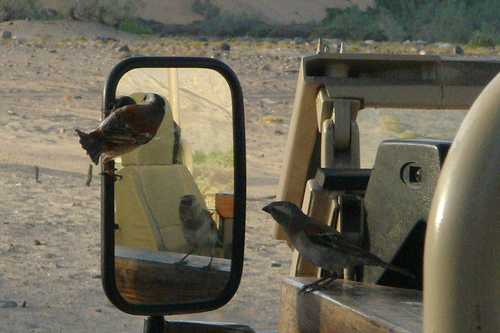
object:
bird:
[72, 92, 164, 182]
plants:
[465, 29, 496, 50]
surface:
[421, 70, 499, 332]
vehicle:
[98, 53, 500, 333]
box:
[275, 275, 423, 333]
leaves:
[358, 23, 368, 27]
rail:
[417, 69, 500, 333]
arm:
[143, 318, 254, 332]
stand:
[144, 316, 254, 332]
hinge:
[320, 99, 362, 170]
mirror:
[114, 68, 236, 304]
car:
[271, 38, 499, 332]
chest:
[287, 230, 312, 255]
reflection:
[382, 141, 438, 150]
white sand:
[1, 0, 100, 333]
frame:
[100, 56, 247, 317]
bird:
[261, 200, 418, 295]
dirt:
[0, 118, 102, 333]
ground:
[1, 16, 500, 332]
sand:
[2, 0, 497, 333]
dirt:
[0, 0, 498, 332]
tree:
[309, 6, 390, 41]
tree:
[375, 6, 406, 42]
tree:
[405, 0, 435, 42]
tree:
[409, 1, 448, 42]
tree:
[467, 1, 498, 31]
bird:
[172, 194, 225, 272]